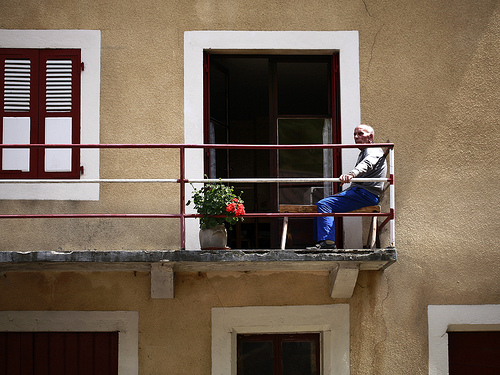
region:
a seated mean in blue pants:
[305, 123, 384, 252]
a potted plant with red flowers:
[185, 173, 246, 250]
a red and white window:
[0, 28, 101, 200]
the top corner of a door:
[0, 308, 140, 373]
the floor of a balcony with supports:
[1, 247, 398, 299]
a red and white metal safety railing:
[0, 141, 397, 248]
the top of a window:
[208, 305, 352, 374]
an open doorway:
[182, 29, 364, 247]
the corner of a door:
[426, 303, 498, 373]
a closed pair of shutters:
[0, 46, 85, 181]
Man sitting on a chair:
[305, 119, 381, 251]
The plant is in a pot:
[188, 180, 245, 250]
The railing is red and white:
[6, 139, 398, 256]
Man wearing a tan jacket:
[344, 122, 385, 194]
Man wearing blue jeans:
[306, 124, 386, 251]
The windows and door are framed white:
[1, 24, 489, 370]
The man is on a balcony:
[1, 127, 398, 302]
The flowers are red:
[218, 189, 245, 221]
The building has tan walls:
[5, 2, 493, 370]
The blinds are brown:
[1, 27, 99, 209]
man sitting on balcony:
[142, 25, 417, 307]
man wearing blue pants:
[311, 176, 381, 238]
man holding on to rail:
[329, 148, 390, 192]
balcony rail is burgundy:
[12, 133, 403, 253]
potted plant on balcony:
[170, 170, 268, 258]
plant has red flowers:
[197, 178, 255, 228]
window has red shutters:
[2, 26, 111, 212]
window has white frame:
[0, 18, 121, 208]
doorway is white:
[145, 22, 410, 279]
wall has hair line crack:
[348, 1, 419, 129]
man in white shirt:
[341, 118, 402, 259]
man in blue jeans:
[310, 174, 385, 251]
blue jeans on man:
[320, 171, 385, 253]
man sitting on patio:
[300, 162, 398, 240]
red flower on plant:
[210, 183, 256, 234]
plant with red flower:
[190, 185, 267, 230]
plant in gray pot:
[176, 178, 264, 274]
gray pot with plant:
[196, 195, 241, 252]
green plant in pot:
[176, 171, 256, 254]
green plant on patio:
[185, 179, 271, 264]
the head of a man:
[339, 117, 394, 162]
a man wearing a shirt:
[310, 145, 399, 216]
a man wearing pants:
[307, 171, 397, 283]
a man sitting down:
[299, 120, 406, 242]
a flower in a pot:
[173, 158, 267, 259]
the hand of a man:
[333, 160, 365, 193]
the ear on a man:
[360, 128, 381, 146]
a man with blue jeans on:
[297, 168, 401, 254]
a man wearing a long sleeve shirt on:
[325, 123, 427, 206]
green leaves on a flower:
[154, 170, 271, 221]